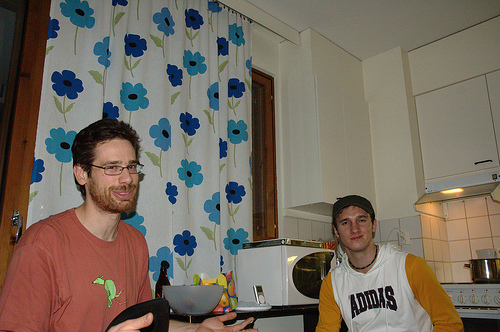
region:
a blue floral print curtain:
[72, 10, 233, 179]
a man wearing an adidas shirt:
[312, 177, 444, 322]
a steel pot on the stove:
[442, 249, 498, 278]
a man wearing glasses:
[57, 112, 166, 234]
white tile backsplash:
[399, 213, 499, 252]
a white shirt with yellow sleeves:
[299, 254, 499, 327]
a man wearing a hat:
[296, 191, 441, 291]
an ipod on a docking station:
[230, 274, 275, 313]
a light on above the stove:
[407, 160, 499, 244]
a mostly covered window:
[176, 32, 324, 252]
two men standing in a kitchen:
[3, 123, 461, 328]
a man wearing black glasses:
[73, 156, 145, 174]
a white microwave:
[236, 242, 333, 306]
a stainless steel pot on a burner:
[464, 255, 498, 281]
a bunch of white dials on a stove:
[451, 286, 496, 306]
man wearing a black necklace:
[345, 245, 378, 269]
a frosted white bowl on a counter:
[164, 282, 221, 316]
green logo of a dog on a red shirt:
[89, 273, 129, 310]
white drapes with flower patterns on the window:
[26, 0, 253, 306]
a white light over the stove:
[440, 188, 467, 199]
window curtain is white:
[48, 6, 269, 267]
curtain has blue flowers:
[45, 6, 256, 248]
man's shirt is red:
[20, 201, 175, 328]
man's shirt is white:
[302, 251, 426, 328]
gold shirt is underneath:
[309, 266, 468, 325]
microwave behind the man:
[243, 211, 388, 326]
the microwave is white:
[229, 233, 354, 318]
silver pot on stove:
[462, 223, 499, 282]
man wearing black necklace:
[331, 237, 411, 285]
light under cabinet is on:
[423, 177, 488, 205]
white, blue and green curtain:
[8, 8, 262, 313]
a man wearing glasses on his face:
[85, 156, 155, 178]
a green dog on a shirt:
[93, 273, 123, 305]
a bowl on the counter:
[160, 281, 233, 316]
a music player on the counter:
[250, 280, 272, 308]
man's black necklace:
[346, 243, 379, 270]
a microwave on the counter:
[229, 235, 379, 305]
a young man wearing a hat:
[325, 192, 389, 252]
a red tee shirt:
[6, 192, 165, 330]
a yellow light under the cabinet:
[432, 181, 469, 206]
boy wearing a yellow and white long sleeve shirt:
[301, 192, 462, 330]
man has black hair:
[320, 190, 398, 287]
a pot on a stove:
[460, 251, 498, 288]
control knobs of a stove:
[447, 279, 496, 309]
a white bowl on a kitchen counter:
[159, 276, 226, 318]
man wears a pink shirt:
[9, 117, 260, 329]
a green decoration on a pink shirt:
[0, 211, 159, 328]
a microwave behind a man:
[226, 233, 333, 310]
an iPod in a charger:
[234, 280, 278, 316]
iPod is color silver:
[249, 276, 274, 311]